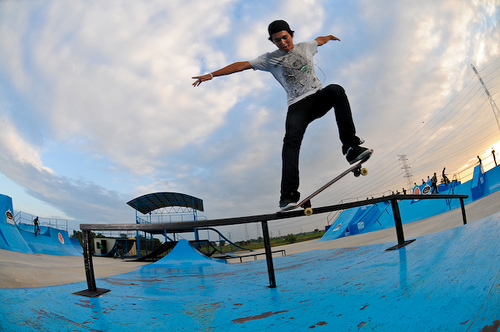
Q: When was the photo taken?
A: Daytime.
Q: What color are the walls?
A: Blue.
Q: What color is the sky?
A: Blue.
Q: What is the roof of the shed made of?
A: Tin.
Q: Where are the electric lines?
A: In the air.